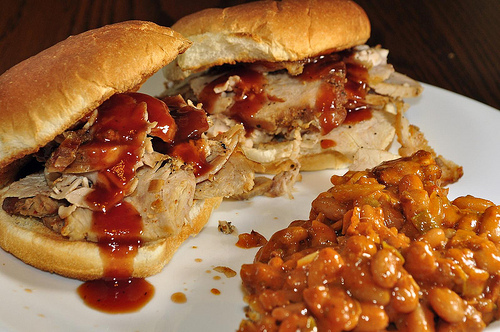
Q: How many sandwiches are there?
A: Two.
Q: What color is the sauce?
A: Red.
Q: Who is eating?
A: No one.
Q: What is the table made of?
A: Wood.